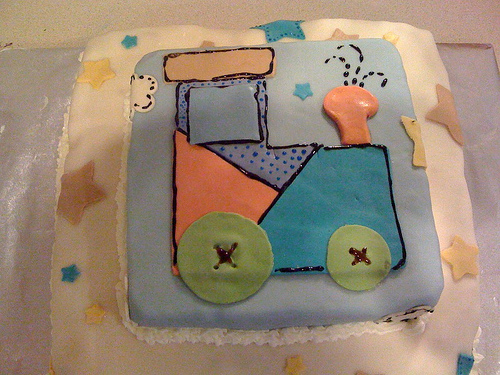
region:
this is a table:
[32, 10, 66, 27]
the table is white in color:
[13, 5, 50, 25]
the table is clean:
[8, 8, 48, 29]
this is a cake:
[48, 24, 497, 372]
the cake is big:
[55, 27, 479, 361]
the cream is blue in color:
[133, 141, 163, 190]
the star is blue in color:
[255, 20, 310, 40]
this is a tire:
[318, 225, 399, 285]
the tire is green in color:
[335, 267, 348, 282]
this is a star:
[443, 231, 490, 295]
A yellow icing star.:
[76, 55, 118, 92]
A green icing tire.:
[171, 210, 276, 310]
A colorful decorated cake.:
[50, 16, 483, 372]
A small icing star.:
[289, 80, 315, 100]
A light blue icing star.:
[250, 18, 316, 43]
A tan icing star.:
[424, 80, 463, 150]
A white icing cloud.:
[128, 71, 159, 114]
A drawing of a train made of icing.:
[160, 40, 410, 305]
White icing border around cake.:
[128, 324, 404, 346]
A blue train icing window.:
[188, 85, 261, 147]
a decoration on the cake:
[309, 227, 391, 314]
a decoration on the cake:
[157, 186, 264, 296]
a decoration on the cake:
[329, 81, 374, 164]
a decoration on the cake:
[178, 127, 278, 262]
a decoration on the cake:
[275, 148, 412, 287]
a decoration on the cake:
[52, 238, 97, 292]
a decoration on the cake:
[42, 155, 122, 214]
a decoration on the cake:
[400, 110, 438, 182]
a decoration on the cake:
[430, 71, 473, 158]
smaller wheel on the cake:
[326, 230, 399, 295]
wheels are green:
[191, 220, 384, 290]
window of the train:
[193, 91, 265, 146]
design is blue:
[188, 96, 281, 141]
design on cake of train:
[185, 48, 409, 306]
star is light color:
[436, 238, 481, 279]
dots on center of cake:
[206, 137, 315, 184]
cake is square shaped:
[48, 33, 485, 374]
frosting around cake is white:
[103, 128, 416, 340]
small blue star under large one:
[56, 255, 75, 290]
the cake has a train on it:
[156, 47, 411, 301]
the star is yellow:
[80, 54, 111, 91]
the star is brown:
[54, 159, 109, 230]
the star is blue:
[55, 259, 82, 289]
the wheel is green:
[172, 208, 285, 310]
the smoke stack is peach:
[321, 78, 381, 145]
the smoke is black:
[324, 44, 378, 84]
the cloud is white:
[135, 83, 149, 99]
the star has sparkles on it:
[246, 20, 288, 45]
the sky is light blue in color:
[140, 141, 172, 187]